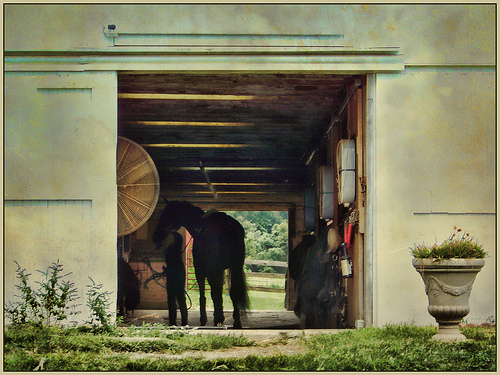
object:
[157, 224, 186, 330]
person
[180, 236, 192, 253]
strap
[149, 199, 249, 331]
horse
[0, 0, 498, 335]
stable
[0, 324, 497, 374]
grass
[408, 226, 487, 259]
grass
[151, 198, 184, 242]
head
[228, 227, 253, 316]
tail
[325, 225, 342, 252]
objects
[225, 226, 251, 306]
hair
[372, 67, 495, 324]
wall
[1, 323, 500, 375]
ground